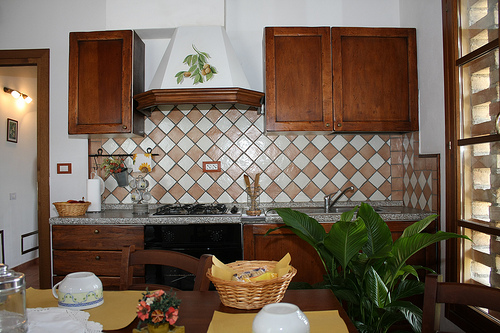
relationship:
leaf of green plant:
[271, 203, 337, 262] [262, 195, 474, 330]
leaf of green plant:
[326, 215, 372, 272] [262, 195, 474, 330]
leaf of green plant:
[386, 229, 472, 279] [262, 195, 474, 330]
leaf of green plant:
[400, 212, 438, 241] [262, 195, 474, 330]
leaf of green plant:
[366, 265, 398, 312] [262, 195, 474, 330]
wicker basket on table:
[202, 256, 299, 313] [0, 285, 360, 331]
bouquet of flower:
[137, 287, 182, 329] [135, 301, 153, 321]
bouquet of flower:
[137, 287, 182, 329] [151, 308, 168, 323]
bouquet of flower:
[137, 287, 182, 329] [166, 303, 183, 324]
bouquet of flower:
[137, 287, 182, 329] [143, 294, 155, 305]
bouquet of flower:
[137, 287, 182, 329] [146, 288, 167, 299]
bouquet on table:
[137, 287, 182, 329] [0, 285, 360, 331]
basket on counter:
[51, 197, 92, 218] [43, 196, 435, 232]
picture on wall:
[5, 115, 20, 145] [0, 61, 40, 277]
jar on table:
[0, 275, 47, 330] [3, 282, 399, 327]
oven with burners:
[141, 202, 244, 290] [199, 203, 227, 214]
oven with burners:
[141, 202, 244, 290] [155, 202, 192, 212]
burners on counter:
[199, 203, 227, 214] [44, 197, 434, 225]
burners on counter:
[155, 202, 192, 212] [44, 197, 434, 225]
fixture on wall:
[3, 82, 21, 106] [4, 74, 36, 256]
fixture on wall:
[19, 89, 36, 111] [4, 74, 36, 256]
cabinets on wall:
[261, 18, 436, 148] [6, 8, 445, 288]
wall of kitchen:
[6, 8, 445, 288] [6, 6, 496, 327]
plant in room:
[274, 190, 456, 322] [0, 0, 498, 332]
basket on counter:
[54, 197, 94, 215] [47, 199, 437, 219]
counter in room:
[47, 199, 437, 219] [0, 0, 498, 332]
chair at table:
[121, 243, 213, 283] [6, 280, 362, 330]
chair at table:
[416, 269, 498, 331] [6, 280, 362, 330]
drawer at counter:
[50, 224, 142, 249] [49, 202, 436, 289]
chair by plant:
[416, 269, 498, 331] [266, 200, 475, 331]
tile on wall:
[87, 101, 404, 202] [0, 1, 405, 217]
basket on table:
[201, 258, 300, 307] [6, 280, 362, 330]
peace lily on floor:
[261, 197, 458, 327] [6, 264, 49, 288]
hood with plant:
[141, 22, 271, 112] [174, 46, 220, 85]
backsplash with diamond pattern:
[88, 102, 439, 212] [219, 109, 260, 151]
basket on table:
[209, 254, 299, 307] [0, 285, 360, 331]